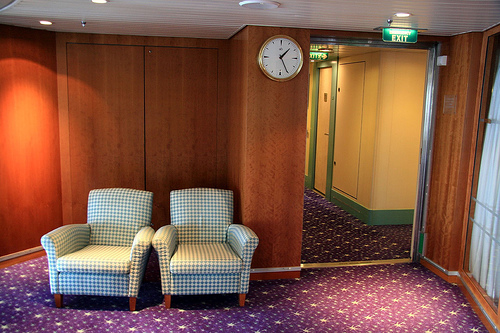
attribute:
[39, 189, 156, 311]
chair — checkered, plaid, gingham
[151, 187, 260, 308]
chair — checkered, plaid, gingham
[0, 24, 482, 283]
walls — wooden, yellow, brown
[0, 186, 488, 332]
floor — carpeted, designed, purple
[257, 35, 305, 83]
clock — white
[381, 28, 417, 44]
sign — green, lighted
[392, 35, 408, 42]
exit — white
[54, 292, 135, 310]
legs — wooden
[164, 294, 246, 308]
legs — wooden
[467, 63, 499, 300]
curtain — white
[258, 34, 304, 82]
trim — gold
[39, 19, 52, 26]
light — white, round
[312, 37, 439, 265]
moulding — green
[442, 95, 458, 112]
plate — gold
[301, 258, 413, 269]
trim — gold, brass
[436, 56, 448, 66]
box — white